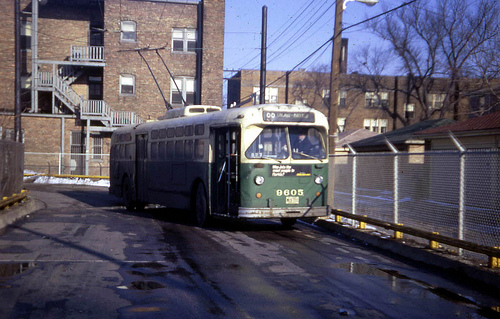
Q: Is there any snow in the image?
A: Yes, there is snow.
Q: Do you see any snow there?
A: Yes, there is snow.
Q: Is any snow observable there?
A: Yes, there is snow.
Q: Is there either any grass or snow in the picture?
A: Yes, there is snow.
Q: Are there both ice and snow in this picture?
A: No, there is snow but no ice.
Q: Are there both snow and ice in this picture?
A: No, there is snow but no ice.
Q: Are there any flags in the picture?
A: No, there are no flags.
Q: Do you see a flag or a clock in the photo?
A: No, there are no flags or clocks.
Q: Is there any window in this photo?
A: Yes, there is a window.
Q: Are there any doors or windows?
A: Yes, there is a window.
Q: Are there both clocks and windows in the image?
A: No, there is a window but no clocks.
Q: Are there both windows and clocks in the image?
A: No, there is a window but no clocks.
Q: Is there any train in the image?
A: No, there are no trains.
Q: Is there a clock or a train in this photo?
A: No, there are no trains or clocks.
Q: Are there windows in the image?
A: Yes, there is a window.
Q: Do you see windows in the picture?
A: Yes, there is a window.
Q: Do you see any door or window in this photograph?
A: Yes, there is a window.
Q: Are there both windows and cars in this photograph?
A: No, there is a window but no cars.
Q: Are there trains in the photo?
A: No, there are no trains.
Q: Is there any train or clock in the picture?
A: No, there are no trains or clocks.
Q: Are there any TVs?
A: No, there are no tvs.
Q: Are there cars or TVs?
A: No, there are no TVs or cars.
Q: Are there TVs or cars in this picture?
A: No, there are no TVs or cars.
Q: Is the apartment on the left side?
A: Yes, the apartment is on the left of the image.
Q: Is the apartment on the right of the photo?
A: No, the apartment is on the left of the image.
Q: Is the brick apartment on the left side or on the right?
A: The apartment is on the left of the image.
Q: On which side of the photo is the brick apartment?
A: The apartment is on the left of the image.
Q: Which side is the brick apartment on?
A: The apartment is on the left of the image.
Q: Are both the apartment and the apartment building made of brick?
A: Yes, both the apartment and the apartment building are made of brick.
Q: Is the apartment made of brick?
A: Yes, the apartment is made of brick.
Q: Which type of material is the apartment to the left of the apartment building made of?
A: The apartment is made of brick.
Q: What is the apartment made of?
A: The apartment is made of brick.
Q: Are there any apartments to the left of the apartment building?
A: Yes, there is an apartment to the left of the apartment building.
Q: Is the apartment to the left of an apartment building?
A: Yes, the apartment is to the left of an apartment building.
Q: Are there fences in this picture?
A: Yes, there is a fence.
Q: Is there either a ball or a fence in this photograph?
A: Yes, there is a fence.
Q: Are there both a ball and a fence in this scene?
A: No, there is a fence but no balls.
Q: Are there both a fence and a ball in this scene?
A: No, there is a fence but no balls.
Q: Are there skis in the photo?
A: No, there are no skis.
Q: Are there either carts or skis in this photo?
A: No, there are no skis or carts.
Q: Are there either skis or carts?
A: No, there are no skis or carts.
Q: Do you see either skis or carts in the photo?
A: No, there are no skis or carts.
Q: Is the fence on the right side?
A: Yes, the fence is on the right of the image.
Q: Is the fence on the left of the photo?
A: No, the fence is on the right of the image.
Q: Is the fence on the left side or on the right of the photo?
A: The fence is on the right of the image.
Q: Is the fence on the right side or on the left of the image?
A: The fence is on the right of the image.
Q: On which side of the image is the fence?
A: The fence is on the right of the image.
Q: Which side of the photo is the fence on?
A: The fence is on the right of the image.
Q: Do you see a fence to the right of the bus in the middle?
A: Yes, there is a fence to the right of the bus.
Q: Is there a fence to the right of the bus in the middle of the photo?
A: Yes, there is a fence to the right of the bus.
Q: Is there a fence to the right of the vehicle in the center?
A: Yes, there is a fence to the right of the bus.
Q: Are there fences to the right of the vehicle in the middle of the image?
A: Yes, there is a fence to the right of the bus.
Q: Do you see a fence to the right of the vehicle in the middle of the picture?
A: Yes, there is a fence to the right of the bus.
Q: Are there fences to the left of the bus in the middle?
A: No, the fence is to the right of the bus.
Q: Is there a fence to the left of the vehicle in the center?
A: No, the fence is to the right of the bus.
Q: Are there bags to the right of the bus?
A: No, there is a fence to the right of the bus.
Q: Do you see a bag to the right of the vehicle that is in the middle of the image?
A: No, there is a fence to the right of the bus.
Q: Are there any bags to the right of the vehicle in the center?
A: No, there is a fence to the right of the bus.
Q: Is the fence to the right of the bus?
A: Yes, the fence is to the right of the bus.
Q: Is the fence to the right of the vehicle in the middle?
A: Yes, the fence is to the right of the bus.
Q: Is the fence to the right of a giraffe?
A: No, the fence is to the right of the bus.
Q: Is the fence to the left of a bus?
A: No, the fence is to the right of a bus.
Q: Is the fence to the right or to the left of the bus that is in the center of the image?
A: The fence is to the right of the bus.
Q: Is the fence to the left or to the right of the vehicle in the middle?
A: The fence is to the right of the bus.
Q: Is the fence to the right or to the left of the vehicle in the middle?
A: The fence is to the right of the bus.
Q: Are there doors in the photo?
A: Yes, there is a door.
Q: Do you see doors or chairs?
A: Yes, there is a door.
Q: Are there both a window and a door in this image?
A: Yes, there are both a door and a window.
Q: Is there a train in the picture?
A: No, there are no trains.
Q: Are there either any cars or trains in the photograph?
A: No, there are no trains or cars.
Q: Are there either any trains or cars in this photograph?
A: No, there are no trains or cars.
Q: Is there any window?
A: Yes, there is a window.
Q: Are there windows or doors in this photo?
A: Yes, there is a window.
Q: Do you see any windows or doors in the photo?
A: Yes, there is a window.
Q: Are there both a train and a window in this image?
A: No, there is a window but no trains.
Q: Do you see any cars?
A: No, there are no cars.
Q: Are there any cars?
A: No, there are no cars.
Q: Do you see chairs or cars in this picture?
A: No, there are no cars or chairs.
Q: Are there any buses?
A: Yes, there is a bus.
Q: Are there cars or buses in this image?
A: Yes, there is a bus.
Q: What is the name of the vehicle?
A: The vehicle is a bus.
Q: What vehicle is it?
A: The vehicle is a bus.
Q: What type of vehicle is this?
A: That is a bus.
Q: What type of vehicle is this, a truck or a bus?
A: That is a bus.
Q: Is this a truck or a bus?
A: This is a bus.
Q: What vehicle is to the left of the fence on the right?
A: The vehicle is a bus.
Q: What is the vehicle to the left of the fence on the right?
A: The vehicle is a bus.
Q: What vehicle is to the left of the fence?
A: The vehicle is a bus.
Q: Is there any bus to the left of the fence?
A: Yes, there is a bus to the left of the fence.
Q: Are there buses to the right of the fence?
A: No, the bus is to the left of the fence.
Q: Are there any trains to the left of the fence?
A: No, there is a bus to the left of the fence.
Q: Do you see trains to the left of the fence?
A: No, there is a bus to the left of the fence.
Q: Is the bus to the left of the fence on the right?
A: Yes, the bus is to the left of the fence.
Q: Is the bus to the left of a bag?
A: No, the bus is to the left of the fence.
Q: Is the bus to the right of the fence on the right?
A: No, the bus is to the left of the fence.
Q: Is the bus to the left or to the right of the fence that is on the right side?
A: The bus is to the left of the fence.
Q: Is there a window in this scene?
A: Yes, there is a window.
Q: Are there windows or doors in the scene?
A: Yes, there is a window.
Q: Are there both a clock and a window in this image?
A: No, there is a window but no clocks.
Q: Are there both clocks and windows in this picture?
A: No, there is a window but no clocks.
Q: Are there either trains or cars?
A: No, there are no cars or trains.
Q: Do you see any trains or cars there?
A: No, there are no cars or trains.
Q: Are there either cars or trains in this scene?
A: No, there are no cars or trains.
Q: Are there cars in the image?
A: No, there are no cars.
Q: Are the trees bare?
A: Yes, the trees are bare.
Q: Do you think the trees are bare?
A: Yes, the trees are bare.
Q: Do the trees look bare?
A: Yes, the trees are bare.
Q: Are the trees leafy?
A: No, the trees are bare.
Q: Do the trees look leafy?
A: No, the trees are bare.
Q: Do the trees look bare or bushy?
A: The trees are bare.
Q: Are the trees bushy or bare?
A: The trees are bare.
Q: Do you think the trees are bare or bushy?
A: The trees are bare.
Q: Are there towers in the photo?
A: No, there are no towers.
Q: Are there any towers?
A: No, there are no towers.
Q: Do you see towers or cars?
A: No, there are no towers or cars.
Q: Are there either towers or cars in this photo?
A: No, there are no towers or cars.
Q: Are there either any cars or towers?
A: No, there are no towers or cars.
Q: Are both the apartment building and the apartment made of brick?
A: Yes, both the apartment building and the apartment are made of brick.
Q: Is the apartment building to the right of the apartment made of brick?
A: Yes, the apartment building is made of brick.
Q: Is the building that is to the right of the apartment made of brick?
A: Yes, the apartment building is made of brick.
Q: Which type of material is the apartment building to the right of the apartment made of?
A: The apartment building is made of brick.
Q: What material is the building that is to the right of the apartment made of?
A: The apartment building is made of brick.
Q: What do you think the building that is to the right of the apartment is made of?
A: The apartment building is made of brick.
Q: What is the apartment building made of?
A: The apartment building is made of brick.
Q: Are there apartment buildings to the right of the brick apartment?
A: Yes, there is an apartment building to the right of the apartment.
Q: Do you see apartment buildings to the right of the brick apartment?
A: Yes, there is an apartment building to the right of the apartment.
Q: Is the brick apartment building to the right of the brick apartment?
A: Yes, the apartment building is to the right of the apartment.